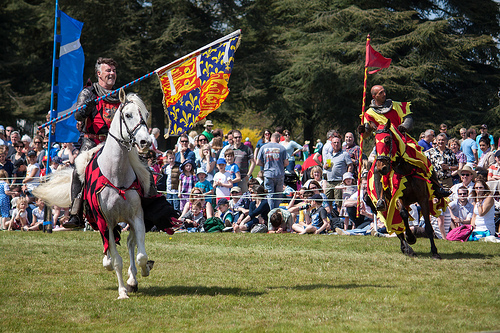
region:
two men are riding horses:
[12, 28, 467, 295]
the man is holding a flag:
[2, 42, 254, 169]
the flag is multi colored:
[118, 22, 275, 155]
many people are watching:
[167, 108, 368, 269]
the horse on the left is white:
[18, 14, 218, 295]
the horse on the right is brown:
[305, 37, 445, 268]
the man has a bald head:
[352, 69, 396, 112]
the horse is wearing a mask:
[357, 112, 413, 169]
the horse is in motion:
[328, 42, 463, 268]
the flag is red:
[339, 21, 400, 87]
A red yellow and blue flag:
[153, 25, 241, 137]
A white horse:
[29, 85, 155, 301]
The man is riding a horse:
[357, 83, 444, 256]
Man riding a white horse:
[33, 55, 159, 300]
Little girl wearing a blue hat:
[176, 158, 198, 217]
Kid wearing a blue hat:
[211, 157, 233, 208]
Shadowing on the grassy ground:
[135, 280, 266, 301]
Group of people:
[1, 123, 47, 230]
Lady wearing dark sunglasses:
[6, 138, 26, 208]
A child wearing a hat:
[339, 170, 357, 233]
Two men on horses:
[28, 55, 442, 302]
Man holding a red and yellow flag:
[353, 32, 415, 224]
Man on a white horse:
[33, 57, 155, 303]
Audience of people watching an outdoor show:
[0, 115, 496, 241]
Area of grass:
[3, 227, 498, 331]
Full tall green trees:
[3, 1, 496, 136]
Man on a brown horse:
[355, 84, 442, 259]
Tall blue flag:
[41, 0, 85, 236]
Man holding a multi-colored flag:
[38, 26, 238, 144]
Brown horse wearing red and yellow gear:
[363, 122, 439, 259]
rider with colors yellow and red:
[354, 30, 453, 213]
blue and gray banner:
[41, 0, 86, 177]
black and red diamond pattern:
[83, 153, 103, 233]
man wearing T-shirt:
[254, 130, 289, 207]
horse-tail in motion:
[29, 162, 73, 211]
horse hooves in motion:
[101, 249, 156, 302]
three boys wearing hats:
[211, 156, 242, 226]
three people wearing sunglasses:
[448, 162, 495, 237]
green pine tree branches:
[394, 0, 498, 90]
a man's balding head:
[369, 82, 389, 104]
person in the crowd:
[213, 158, 236, 193]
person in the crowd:
[268, 135, 296, 195]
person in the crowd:
[308, 165, 323, 187]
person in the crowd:
[181, 158, 193, 185]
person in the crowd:
[268, 207, 293, 235]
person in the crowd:
[468, 179, 491, 238]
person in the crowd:
[336, 170, 354, 193]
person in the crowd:
[188, 186, 213, 223]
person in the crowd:
[307, 194, 327, 230]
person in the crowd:
[266, 210, 283, 239]